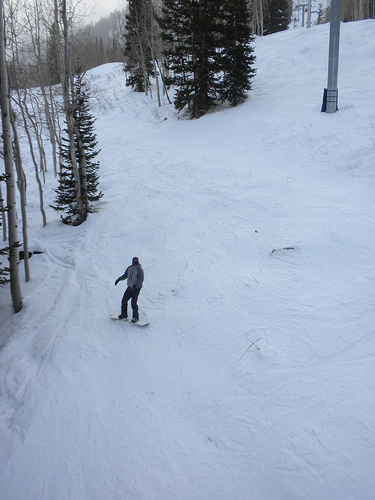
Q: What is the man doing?
A: Snowboarding.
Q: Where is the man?
A: Coming down a hill.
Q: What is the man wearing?
A: A coat and pants.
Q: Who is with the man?
A: No one.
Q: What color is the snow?
A: White.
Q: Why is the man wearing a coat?
A: It is cold outside.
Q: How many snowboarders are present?
A: Only one.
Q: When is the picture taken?
A: During the day.